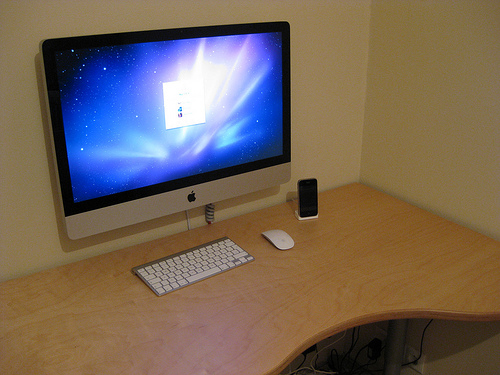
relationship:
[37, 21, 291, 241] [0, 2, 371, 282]
computer on wall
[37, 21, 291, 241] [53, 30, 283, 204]
computer has screen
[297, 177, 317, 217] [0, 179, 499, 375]
cellphone on desk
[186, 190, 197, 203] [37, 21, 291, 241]
logo on computer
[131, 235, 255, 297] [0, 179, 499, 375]
keyboard on desk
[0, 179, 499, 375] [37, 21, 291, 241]
desk under computer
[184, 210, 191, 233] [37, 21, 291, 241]
wire behind computer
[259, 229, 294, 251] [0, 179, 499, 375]
mouse on desk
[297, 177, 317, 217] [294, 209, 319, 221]
cellphone in dock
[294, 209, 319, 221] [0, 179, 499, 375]
dock on desk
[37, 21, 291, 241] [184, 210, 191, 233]
computer has wire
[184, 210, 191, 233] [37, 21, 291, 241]
wire to computer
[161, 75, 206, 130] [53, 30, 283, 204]
message on screen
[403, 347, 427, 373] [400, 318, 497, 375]
outlet on wall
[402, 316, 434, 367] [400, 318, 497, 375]
cord on wall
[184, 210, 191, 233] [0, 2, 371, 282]
wire on wall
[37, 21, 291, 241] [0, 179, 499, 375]
computer on desk